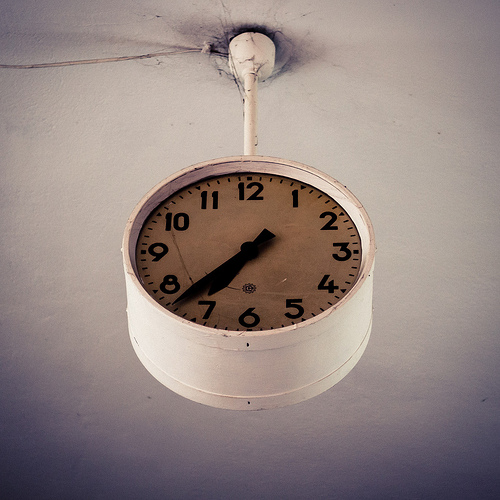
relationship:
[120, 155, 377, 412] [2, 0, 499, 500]
clock hanging from ceiling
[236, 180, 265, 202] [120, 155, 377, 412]
number showing on clock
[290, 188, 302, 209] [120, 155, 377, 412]
number showing on clock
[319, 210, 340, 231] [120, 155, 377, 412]
number showing on clock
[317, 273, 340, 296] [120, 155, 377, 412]
number showing on clock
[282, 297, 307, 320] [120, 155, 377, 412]
number showing on clock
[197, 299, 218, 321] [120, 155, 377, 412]
number showing on clock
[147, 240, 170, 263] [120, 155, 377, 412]
number showing on clock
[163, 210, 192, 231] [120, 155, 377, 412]
number showing on clock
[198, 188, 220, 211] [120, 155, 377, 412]
number showing on clock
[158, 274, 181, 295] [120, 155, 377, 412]
number showing on clock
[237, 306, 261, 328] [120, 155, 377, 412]
number showing on clock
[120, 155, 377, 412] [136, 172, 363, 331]
clock has face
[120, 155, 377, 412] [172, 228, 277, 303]
clock has hand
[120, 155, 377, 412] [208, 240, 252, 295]
clock has hand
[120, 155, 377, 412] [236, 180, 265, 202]
clock has number